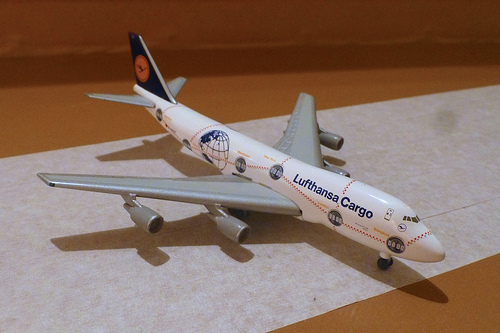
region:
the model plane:
[42, 19, 447, 279]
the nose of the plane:
[425, 238, 451, 273]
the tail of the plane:
[85, 18, 200, 127]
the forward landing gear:
[372, 255, 397, 272]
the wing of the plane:
[27, 165, 293, 217]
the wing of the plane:
[258, 80, 328, 171]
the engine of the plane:
[110, 186, 165, 235]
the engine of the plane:
[212, 207, 249, 244]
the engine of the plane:
[316, 150, 348, 177]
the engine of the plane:
[314, 115, 349, 153]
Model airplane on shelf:
[36, 31, 444, 271]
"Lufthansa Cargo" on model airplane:
[292, 173, 372, 221]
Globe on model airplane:
[195, 128, 232, 170]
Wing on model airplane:
[40, 173, 300, 245]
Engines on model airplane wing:
[123, 193, 248, 244]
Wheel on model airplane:
[376, 253, 394, 270]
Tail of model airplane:
[87, 33, 183, 121]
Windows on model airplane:
[402, 212, 420, 223]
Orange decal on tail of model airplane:
[135, 54, 150, 81]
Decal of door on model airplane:
[382, 207, 393, 221]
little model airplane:
[37, 25, 453, 271]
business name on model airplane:
[290, 170, 380, 231]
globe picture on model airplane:
[190, 128, 233, 169]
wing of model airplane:
[35, 167, 305, 247]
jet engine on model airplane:
[120, 200, 168, 240]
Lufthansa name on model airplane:
[285, 170, 375, 227]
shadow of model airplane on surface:
[67, 205, 327, 263]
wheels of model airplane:
[370, 250, 397, 273]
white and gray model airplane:
[35, 28, 465, 278]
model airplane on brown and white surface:
[46, 73, 479, 280]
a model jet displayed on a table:
[36, 29, 445, 269]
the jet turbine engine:
[119, 195, 163, 235]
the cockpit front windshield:
[402, 213, 420, 225]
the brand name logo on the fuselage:
[293, 173, 374, 221]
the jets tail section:
[127, 31, 176, 102]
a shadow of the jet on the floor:
[48, 210, 270, 265]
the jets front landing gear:
[373, 250, 394, 271]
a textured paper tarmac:
[0, 245, 273, 331]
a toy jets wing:
[36, 170, 302, 243]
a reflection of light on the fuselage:
[357, 186, 390, 211]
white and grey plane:
[38, 33, 445, 280]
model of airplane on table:
[36, 32, 446, 280]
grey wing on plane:
[40, 168, 301, 215]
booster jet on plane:
[126, 199, 164, 235]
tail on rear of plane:
[84, 33, 189, 114]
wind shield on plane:
[403, 216, 420, 223]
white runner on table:
[5, 81, 497, 331]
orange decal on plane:
[133, 54, 150, 84]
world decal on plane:
[198, 128, 228, 173]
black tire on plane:
[376, 256, 393, 272]